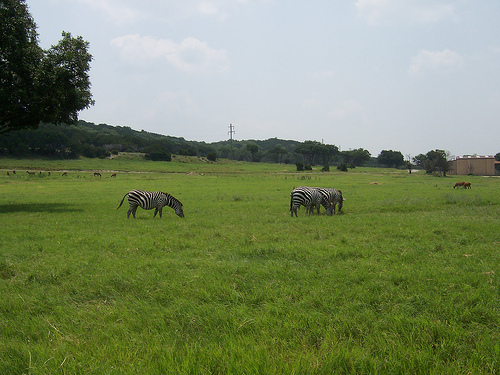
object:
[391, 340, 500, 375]
grass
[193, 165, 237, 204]
grass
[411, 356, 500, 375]
grass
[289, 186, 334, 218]
zebra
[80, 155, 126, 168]
grass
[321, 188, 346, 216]
zebra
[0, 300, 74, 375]
grass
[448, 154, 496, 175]
building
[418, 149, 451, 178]
trees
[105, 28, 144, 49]
cloud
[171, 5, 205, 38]
sky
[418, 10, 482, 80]
sky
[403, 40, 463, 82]
cloud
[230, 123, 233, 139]
pole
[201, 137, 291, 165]
trees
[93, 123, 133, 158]
trees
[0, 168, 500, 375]
field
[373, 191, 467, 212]
grass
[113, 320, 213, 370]
grass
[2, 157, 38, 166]
grass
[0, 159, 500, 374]
open field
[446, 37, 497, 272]
side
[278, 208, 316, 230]
grass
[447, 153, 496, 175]
shed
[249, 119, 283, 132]
cloud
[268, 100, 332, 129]
sky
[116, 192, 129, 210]
tail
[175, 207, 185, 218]
head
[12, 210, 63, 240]
grass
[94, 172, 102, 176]
horse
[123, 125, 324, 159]
bushes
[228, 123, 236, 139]
post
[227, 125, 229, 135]
lines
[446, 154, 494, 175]
premises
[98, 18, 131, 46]
sky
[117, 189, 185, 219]
zebra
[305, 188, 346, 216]
zebra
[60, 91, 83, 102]
leaves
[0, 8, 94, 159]
tree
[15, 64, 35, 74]
leaves